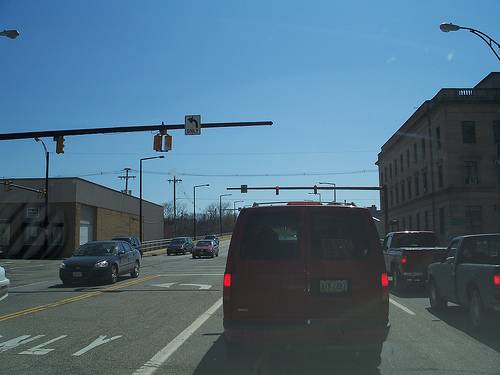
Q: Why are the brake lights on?
A: It has stopped.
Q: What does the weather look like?
A: It looks clear.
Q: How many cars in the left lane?
A: There is none.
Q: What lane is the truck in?
A: It is in the middle lane.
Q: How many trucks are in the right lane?
A: There are two.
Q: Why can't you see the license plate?
A: It is to dark.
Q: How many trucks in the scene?
A: Two.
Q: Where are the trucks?
A: On the right side.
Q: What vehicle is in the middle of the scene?
A: Van.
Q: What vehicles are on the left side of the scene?
A: Cars.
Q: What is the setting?
A: City street.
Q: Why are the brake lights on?
A: The traffic light is red.